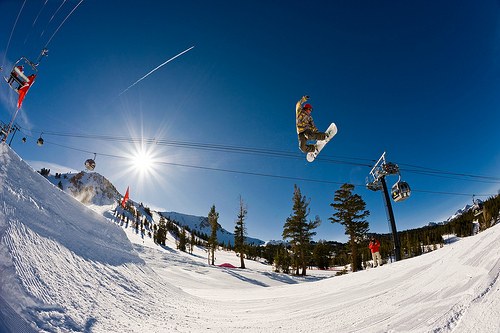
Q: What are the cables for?
A: Ski lift.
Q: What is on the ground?
A: Snow.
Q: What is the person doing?
A: Snowboarding.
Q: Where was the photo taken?
A: Ski slope.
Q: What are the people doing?
A: Snowboarding.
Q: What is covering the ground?
A: Snow.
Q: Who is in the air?
A: The man.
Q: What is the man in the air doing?
A: A trick.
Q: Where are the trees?
A: Lining the mountain.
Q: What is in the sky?
A: The sun.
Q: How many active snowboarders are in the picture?
A: One.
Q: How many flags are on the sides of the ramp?
A: Two.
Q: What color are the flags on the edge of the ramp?
A: Red.